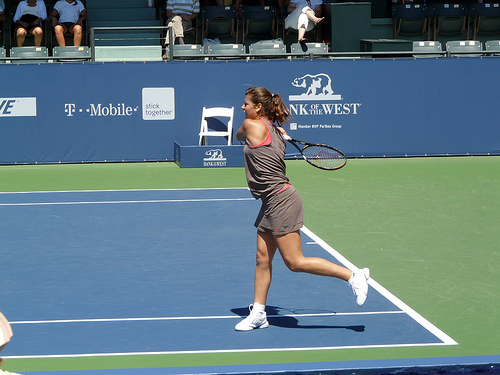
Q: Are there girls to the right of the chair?
A: Yes, there is a girl to the right of the chair.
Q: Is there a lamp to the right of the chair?
A: No, there is a girl to the right of the chair.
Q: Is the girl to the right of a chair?
A: Yes, the girl is to the right of a chair.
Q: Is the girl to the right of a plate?
A: No, the girl is to the right of a chair.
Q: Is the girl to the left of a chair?
A: No, the girl is to the right of a chair.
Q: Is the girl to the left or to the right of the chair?
A: The girl is to the right of the chair.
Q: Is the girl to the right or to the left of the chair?
A: The girl is to the right of the chair.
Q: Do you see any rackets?
A: Yes, there is a racket.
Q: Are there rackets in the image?
A: Yes, there is a racket.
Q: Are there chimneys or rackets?
A: Yes, there is a racket.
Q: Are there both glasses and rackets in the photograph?
A: No, there is a racket but no glasses.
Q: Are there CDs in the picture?
A: No, there are no cds.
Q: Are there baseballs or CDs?
A: No, there are no CDs or baseballs.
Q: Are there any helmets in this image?
A: No, there are no helmets.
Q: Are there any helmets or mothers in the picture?
A: No, there are no helmets or mothers.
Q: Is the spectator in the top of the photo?
A: Yes, the spectator is in the top of the image.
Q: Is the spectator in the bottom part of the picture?
A: No, the spectator is in the top of the image.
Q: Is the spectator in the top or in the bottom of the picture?
A: The spectator is in the top of the image.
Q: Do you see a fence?
A: No, there are no fences.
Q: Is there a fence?
A: No, there are no fences.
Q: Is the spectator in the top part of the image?
A: Yes, the spectator is in the top of the image.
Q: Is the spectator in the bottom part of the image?
A: No, the spectator is in the top of the image.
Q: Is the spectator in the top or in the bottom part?
A: The spectator is in the top of the image.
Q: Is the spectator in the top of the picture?
A: Yes, the spectator is in the top of the image.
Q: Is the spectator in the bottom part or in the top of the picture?
A: The spectator is in the top of the image.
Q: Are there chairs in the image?
A: Yes, there is a chair.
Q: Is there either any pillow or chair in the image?
A: Yes, there is a chair.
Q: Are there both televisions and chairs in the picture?
A: No, there is a chair but no televisions.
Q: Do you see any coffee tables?
A: No, there are no coffee tables.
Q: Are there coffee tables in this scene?
A: No, there are no coffee tables.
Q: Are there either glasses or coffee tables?
A: No, there are no coffee tables or glasses.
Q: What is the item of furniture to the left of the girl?
A: The piece of furniture is a chair.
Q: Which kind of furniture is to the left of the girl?
A: The piece of furniture is a chair.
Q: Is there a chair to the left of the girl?
A: Yes, there is a chair to the left of the girl.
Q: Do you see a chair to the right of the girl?
A: No, the chair is to the left of the girl.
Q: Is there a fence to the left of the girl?
A: No, there is a chair to the left of the girl.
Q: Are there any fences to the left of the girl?
A: No, there is a chair to the left of the girl.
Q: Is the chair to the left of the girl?
A: Yes, the chair is to the left of the girl.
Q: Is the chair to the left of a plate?
A: No, the chair is to the left of the girl.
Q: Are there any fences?
A: No, there are no fences.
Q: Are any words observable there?
A: Yes, there are words.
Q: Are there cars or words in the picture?
A: Yes, there are words.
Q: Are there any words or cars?
A: Yes, there are words.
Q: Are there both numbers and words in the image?
A: No, there are words but no numbers.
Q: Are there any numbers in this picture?
A: No, there are no numbers.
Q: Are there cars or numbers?
A: No, there are no numbers or cars.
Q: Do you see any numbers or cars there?
A: No, there are no numbers or cars.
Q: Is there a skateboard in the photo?
A: No, there are no skateboards.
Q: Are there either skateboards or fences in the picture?
A: No, there are no skateboards or fences.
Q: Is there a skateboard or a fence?
A: No, there are no skateboards or fences.